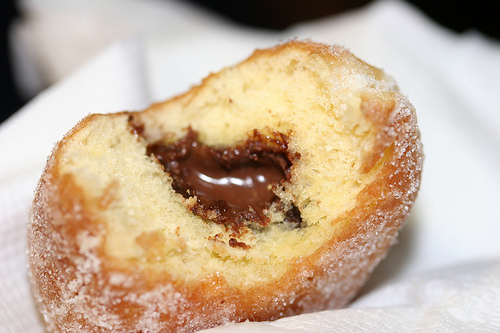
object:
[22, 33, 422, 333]
bread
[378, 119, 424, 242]
sugar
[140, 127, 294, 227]
chocolate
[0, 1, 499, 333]
napkin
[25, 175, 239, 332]
sugar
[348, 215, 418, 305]
shadow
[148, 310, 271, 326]
sugar